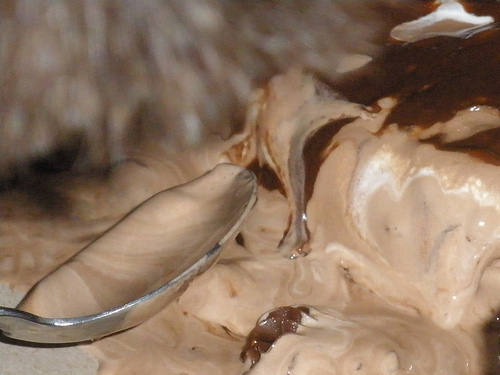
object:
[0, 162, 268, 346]
spoon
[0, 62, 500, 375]
cream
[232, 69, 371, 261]
down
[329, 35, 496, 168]
chocolate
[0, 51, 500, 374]
brown dessert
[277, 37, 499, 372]
ice cream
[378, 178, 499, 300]
light brown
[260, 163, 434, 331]
creamy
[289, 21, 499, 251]
syrup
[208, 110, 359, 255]
chocolate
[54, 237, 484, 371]
vanilla